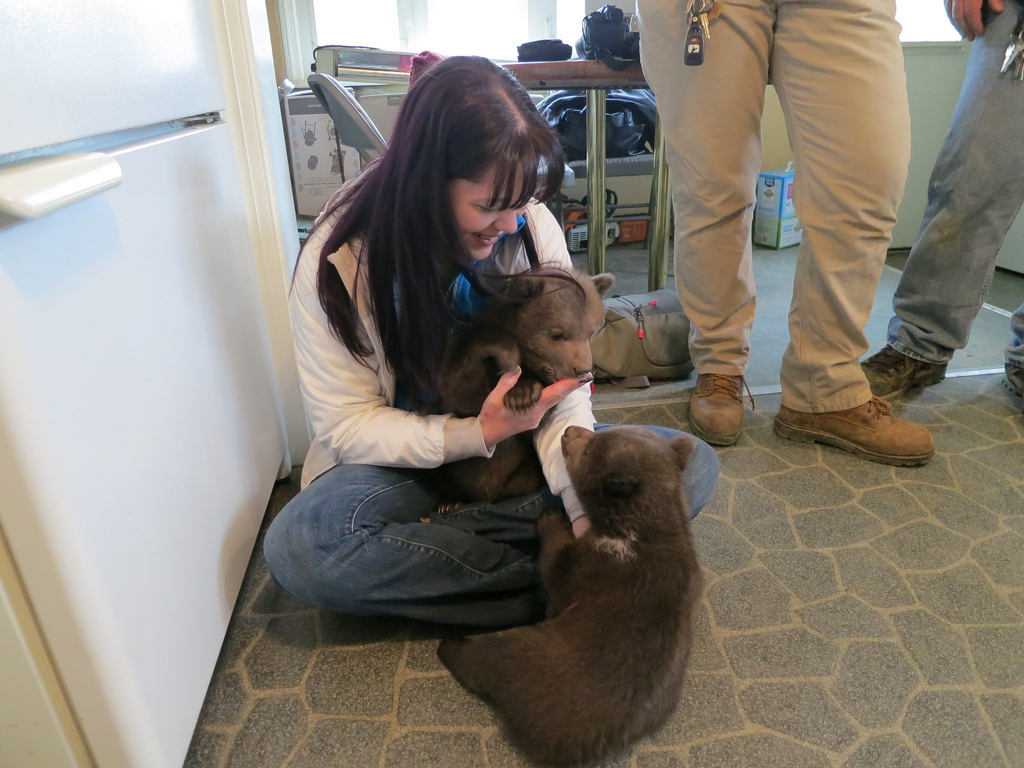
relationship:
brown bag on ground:
[580, 296, 694, 379] [725, 460, 937, 571]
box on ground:
[743, 168, 805, 252] [750, 254, 788, 365]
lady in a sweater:
[260, 54, 599, 628] [264, 80, 690, 614]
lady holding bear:
[303, 46, 699, 603] [392, 242, 637, 506]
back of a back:
[306, 65, 412, 141] [307, 73, 390, 163]